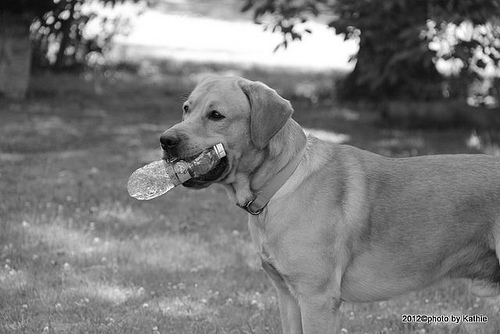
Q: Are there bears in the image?
A: No, there are no bears.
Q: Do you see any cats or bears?
A: No, there are no bears or cats.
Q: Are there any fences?
A: No, there are no fences.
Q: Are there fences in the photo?
A: No, there are no fences.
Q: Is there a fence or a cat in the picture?
A: No, there are no fences or cats.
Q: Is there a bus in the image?
A: No, there are no buses.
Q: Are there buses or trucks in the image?
A: No, there are no buses or trucks.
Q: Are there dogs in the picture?
A: Yes, there is a dog.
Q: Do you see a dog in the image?
A: Yes, there is a dog.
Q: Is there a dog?
A: Yes, there is a dog.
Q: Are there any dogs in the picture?
A: Yes, there is a dog.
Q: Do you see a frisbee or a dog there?
A: Yes, there is a dog.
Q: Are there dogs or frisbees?
A: Yes, there is a dog.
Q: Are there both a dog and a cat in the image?
A: No, there is a dog but no cats.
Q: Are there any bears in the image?
A: No, there are no bears.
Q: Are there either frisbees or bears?
A: No, there are no bears or frisbees.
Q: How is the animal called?
A: The animal is a dog.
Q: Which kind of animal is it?
A: The animal is a dog.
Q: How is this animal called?
A: That is a dog.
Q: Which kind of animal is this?
A: That is a dog.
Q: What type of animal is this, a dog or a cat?
A: That is a dog.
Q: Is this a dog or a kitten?
A: This is a dog.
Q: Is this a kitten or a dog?
A: This is a dog.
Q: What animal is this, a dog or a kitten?
A: This is a dog.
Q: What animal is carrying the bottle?
A: The dog is carrying the bottle.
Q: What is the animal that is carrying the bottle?
A: The animal is a dog.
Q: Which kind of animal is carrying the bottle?
A: The animal is a dog.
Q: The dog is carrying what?
A: The dog is carrying a bottle.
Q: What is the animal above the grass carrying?
A: The dog is carrying a bottle.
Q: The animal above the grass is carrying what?
A: The dog is carrying a bottle.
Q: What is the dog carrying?
A: The dog is carrying a bottle.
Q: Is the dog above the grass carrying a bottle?
A: Yes, the dog is carrying a bottle.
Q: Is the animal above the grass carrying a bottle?
A: Yes, the dog is carrying a bottle.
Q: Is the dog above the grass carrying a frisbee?
A: No, the dog is carrying a bottle.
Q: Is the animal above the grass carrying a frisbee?
A: No, the dog is carrying a bottle.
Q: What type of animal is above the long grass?
A: The animal is a dog.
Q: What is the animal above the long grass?
A: The animal is a dog.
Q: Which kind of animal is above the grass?
A: The animal is a dog.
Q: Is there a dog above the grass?
A: Yes, there is a dog above the grass.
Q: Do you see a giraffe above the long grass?
A: No, there is a dog above the grass.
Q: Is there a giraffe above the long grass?
A: No, there is a dog above the grass.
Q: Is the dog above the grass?
A: Yes, the dog is above the grass.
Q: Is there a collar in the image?
A: Yes, there is a collar.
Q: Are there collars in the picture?
A: Yes, there is a collar.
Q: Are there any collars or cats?
A: Yes, there is a collar.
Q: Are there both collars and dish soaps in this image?
A: No, there is a collar but no dish soaps.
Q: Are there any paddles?
A: No, there are no paddles.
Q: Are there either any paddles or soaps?
A: No, there are no paddles or soaps.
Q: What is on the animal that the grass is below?
A: The collar is on the dog.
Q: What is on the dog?
A: The collar is on the dog.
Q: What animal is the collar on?
A: The collar is on the dog.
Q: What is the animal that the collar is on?
A: The animal is a dog.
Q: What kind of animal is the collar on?
A: The collar is on the dog.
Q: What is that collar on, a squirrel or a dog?
A: The collar is on a dog.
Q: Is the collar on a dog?
A: Yes, the collar is on a dog.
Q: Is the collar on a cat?
A: No, the collar is on a dog.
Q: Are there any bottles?
A: Yes, there is a bottle.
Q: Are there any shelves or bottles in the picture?
A: Yes, there is a bottle.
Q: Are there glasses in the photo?
A: No, there are no glasses.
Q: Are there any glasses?
A: No, there are no glasses.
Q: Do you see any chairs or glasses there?
A: No, there are no glasses or chairs.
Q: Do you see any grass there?
A: Yes, there is grass.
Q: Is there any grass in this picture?
A: Yes, there is grass.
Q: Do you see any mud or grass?
A: Yes, there is grass.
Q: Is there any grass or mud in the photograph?
A: Yes, there is grass.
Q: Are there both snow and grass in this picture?
A: No, there is grass but no snow.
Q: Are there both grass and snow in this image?
A: No, there is grass but no snow.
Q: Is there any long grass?
A: Yes, there is long grass.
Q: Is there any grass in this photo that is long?
A: Yes, there is grass that is long.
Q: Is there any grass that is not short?
A: Yes, there is long grass.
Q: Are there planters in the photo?
A: No, there are no planters.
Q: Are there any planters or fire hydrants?
A: No, there are no planters or fire hydrants.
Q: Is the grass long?
A: Yes, the grass is long.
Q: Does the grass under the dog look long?
A: Yes, the grass is long.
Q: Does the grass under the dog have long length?
A: Yes, the grass is long.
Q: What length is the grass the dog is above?
A: The grass is long.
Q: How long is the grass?
A: The grass is long.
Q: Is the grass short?
A: No, the grass is long.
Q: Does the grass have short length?
A: No, the grass is long.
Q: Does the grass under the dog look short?
A: No, the grass is long.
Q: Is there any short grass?
A: No, there is grass but it is long.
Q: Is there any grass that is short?
A: No, there is grass but it is long.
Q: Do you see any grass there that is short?
A: No, there is grass but it is long.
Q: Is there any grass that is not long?
A: No, there is grass but it is long.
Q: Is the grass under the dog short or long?
A: The grass is long.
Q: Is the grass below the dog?
A: Yes, the grass is below the dog.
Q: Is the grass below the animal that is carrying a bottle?
A: Yes, the grass is below the dog.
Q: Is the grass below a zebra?
A: No, the grass is below the dog.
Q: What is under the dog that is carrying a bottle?
A: The grass is under the dog.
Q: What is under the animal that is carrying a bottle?
A: The grass is under the dog.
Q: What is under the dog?
A: The grass is under the dog.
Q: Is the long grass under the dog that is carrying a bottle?
A: Yes, the grass is under the dog.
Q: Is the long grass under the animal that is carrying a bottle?
A: Yes, the grass is under the dog.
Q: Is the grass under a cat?
A: No, the grass is under the dog.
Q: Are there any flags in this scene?
A: No, there are no flags.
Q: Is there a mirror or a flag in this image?
A: No, there are no flags or mirrors.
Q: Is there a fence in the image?
A: No, there are no fences.